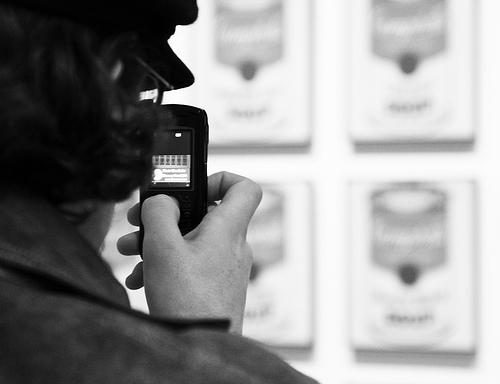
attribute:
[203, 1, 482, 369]
art — blurry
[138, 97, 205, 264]
phone — black, old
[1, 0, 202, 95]
hat — black